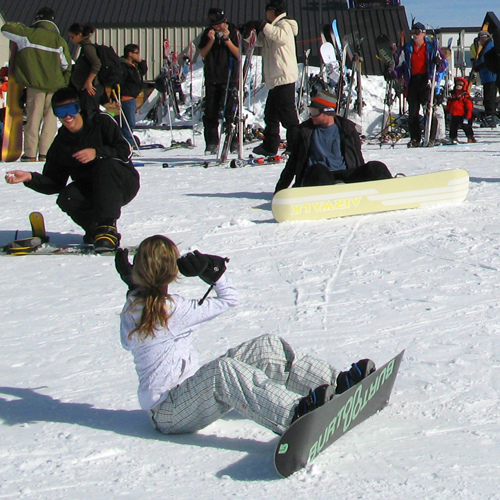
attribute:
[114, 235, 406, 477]
woman — snowboarding, sitting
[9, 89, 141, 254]
man — waiting, smiling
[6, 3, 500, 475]
people — sking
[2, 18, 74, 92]
jacket — white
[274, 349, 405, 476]
snowboard — white, black, yellow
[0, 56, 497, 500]
snow — white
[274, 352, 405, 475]
board — grey, yellow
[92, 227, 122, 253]
boots — black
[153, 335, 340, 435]
pants — white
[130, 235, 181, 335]
hair — long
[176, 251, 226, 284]
gloves — black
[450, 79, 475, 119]
coat — red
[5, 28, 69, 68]
strip — white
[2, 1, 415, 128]
building — white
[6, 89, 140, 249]
person — crouching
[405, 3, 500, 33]
sky — blue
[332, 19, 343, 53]
ski — blue